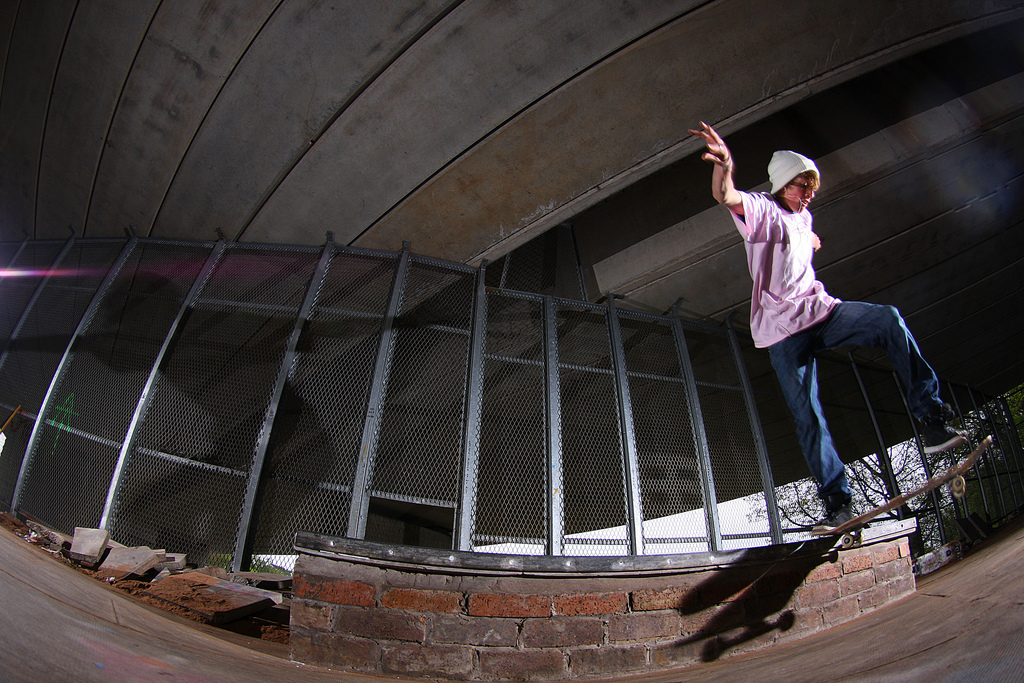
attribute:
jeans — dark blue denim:
[747, 285, 974, 527]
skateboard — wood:
[802, 430, 984, 552]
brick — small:
[274, 509, 925, 680]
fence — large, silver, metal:
[6, 233, 1015, 571]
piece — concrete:
[61, 512, 113, 567]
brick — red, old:
[452, 572, 552, 620]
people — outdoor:
[657, 95, 1014, 538]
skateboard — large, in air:
[678, 497, 1003, 575]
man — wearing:
[663, 124, 966, 608]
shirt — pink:
[714, 238, 875, 353]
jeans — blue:
[751, 309, 950, 521]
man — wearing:
[665, 119, 975, 554]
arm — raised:
[689, 201, 724, 219]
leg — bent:
[747, 336, 847, 503]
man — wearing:
[678, 122, 1000, 578]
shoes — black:
[790, 409, 968, 507]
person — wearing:
[661, 122, 943, 535]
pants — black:
[769, 301, 932, 509]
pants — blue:
[773, 288, 946, 468]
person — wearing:
[686, 145, 985, 550]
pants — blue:
[740, 299, 942, 481]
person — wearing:
[669, 115, 994, 578]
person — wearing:
[691, 223, 968, 587]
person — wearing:
[680, 128, 955, 494]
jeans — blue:
[745, 281, 929, 504]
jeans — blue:
[738, 294, 944, 493]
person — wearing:
[673, 208, 963, 530]